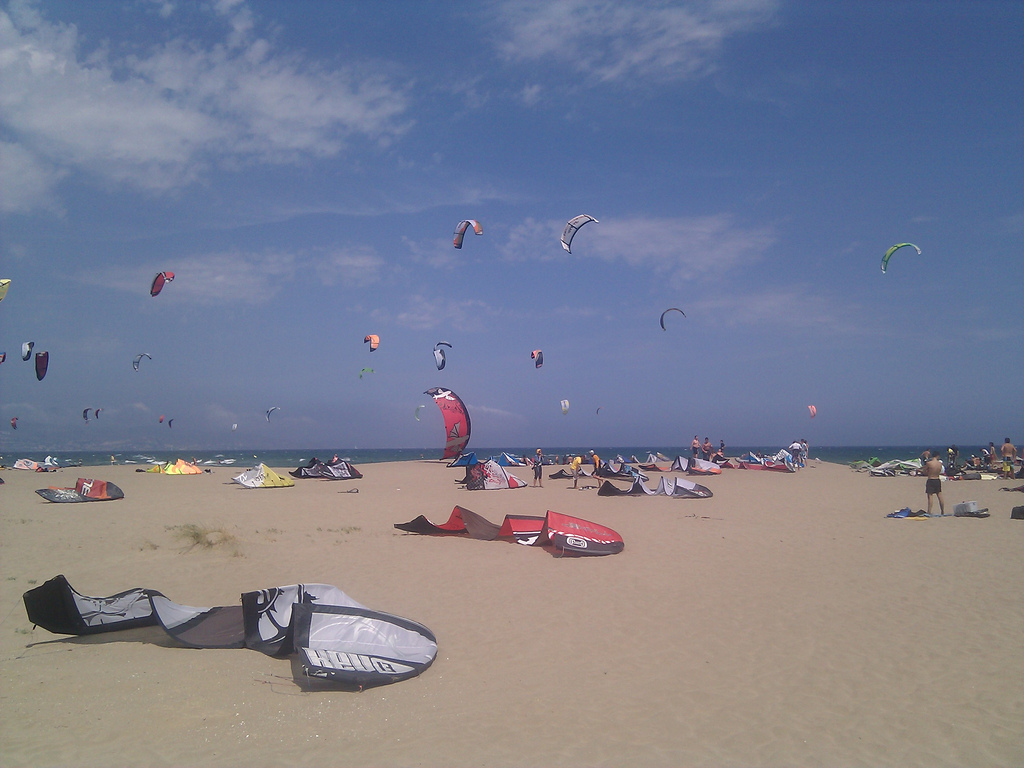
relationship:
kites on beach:
[31, 450, 819, 704] [0, 458, 1024, 768]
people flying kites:
[512, 433, 977, 520] [0, 223, 949, 438]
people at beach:
[512, 433, 977, 520] [67, 449, 990, 734]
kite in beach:
[22, 575, 447, 731] [0, 458, 1024, 768]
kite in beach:
[400, 493, 626, 569] [0, 458, 1024, 768]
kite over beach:
[420, 371, 477, 471] [0, 458, 1024, 768]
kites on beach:
[0, 450, 1022, 675] [0, 458, 1024, 768]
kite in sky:
[876, 233, 928, 282] [1, 1, 1023, 448]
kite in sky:
[554, 209, 599, 260] [1, 1, 1023, 448]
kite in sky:
[447, 216, 486, 252] [1, 1, 1023, 448]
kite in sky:
[146, 270, 178, 297] [1, 1, 1023, 448]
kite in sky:
[31, 352, 51, 382] [1, 1, 1023, 448]